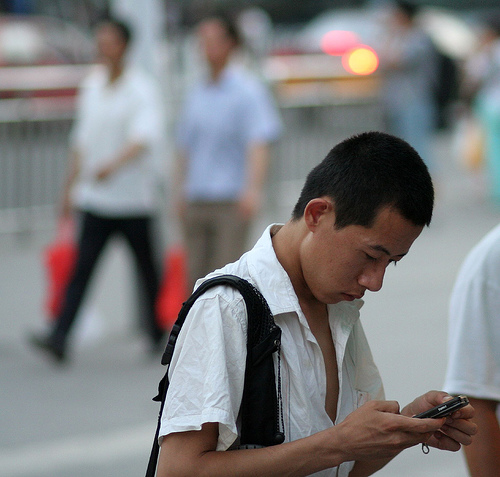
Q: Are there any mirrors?
A: No, there are no mirrors.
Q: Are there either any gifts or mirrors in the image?
A: No, there are no mirrors or gifts.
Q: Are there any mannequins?
A: No, there are no mannequins.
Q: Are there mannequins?
A: No, there are no mannequins.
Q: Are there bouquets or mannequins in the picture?
A: No, there are no mannequins or bouquets.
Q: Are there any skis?
A: No, there are no skis.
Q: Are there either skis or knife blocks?
A: No, there are no skis or knife blocks.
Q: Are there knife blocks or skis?
A: No, there are no skis or knife blocks.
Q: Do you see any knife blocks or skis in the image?
A: No, there are no skis or knife blocks.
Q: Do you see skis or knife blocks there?
A: No, there are no skis or knife blocks.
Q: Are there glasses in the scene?
A: No, there are no glasses.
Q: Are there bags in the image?
A: Yes, there is a bag.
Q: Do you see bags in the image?
A: Yes, there is a bag.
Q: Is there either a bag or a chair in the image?
A: Yes, there is a bag.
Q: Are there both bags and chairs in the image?
A: No, there is a bag but no chairs.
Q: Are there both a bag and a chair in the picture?
A: No, there is a bag but no chairs.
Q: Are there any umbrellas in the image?
A: No, there are no umbrellas.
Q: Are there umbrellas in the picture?
A: No, there are no umbrellas.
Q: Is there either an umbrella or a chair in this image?
A: No, there are no umbrellas or chairs.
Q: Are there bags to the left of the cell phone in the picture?
A: Yes, there is a bag to the left of the cell phone.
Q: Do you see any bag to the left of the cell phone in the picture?
A: Yes, there is a bag to the left of the cell phone.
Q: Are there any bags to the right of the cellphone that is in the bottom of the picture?
A: No, the bag is to the left of the cell phone.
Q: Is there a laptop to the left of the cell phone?
A: No, there is a bag to the left of the cell phone.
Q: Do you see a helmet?
A: No, there are no helmets.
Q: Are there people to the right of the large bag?
A: Yes, there is a person to the right of the bag.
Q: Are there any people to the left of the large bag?
A: No, the person is to the right of the bag.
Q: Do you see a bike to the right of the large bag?
A: No, there is a person to the right of the bag.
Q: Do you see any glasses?
A: No, there are no glasses.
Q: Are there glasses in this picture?
A: No, there are no glasses.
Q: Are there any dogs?
A: No, there are no dogs.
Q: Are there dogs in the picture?
A: No, there are no dogs.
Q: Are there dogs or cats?
A: No, there are no dogs or cats.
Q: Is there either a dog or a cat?
A: No, there are no dogs or cats.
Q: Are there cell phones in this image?
A: Yes, there is a cell phone.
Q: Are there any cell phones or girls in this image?
A: Yes, there is a cell phone.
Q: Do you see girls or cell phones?
A: Yes, there is a cell phone.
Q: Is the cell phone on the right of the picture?
A: Yes, the cell phone is on the right of the image.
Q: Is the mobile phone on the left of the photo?
A: No, the mobile phone is on the right of the image.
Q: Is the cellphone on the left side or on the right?
A: The cellphone is on the right of the image.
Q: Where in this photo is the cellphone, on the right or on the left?
A: The cellphone is on the right of the image.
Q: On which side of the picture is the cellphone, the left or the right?
A: The cellphone is on the right of the image.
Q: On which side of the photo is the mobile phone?
A: The mobile phone is on the right of the image.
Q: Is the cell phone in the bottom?
A: Yes, the cell phone is in the bottom of the image.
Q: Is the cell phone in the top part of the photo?
A: No, the cell phone is in the bottom of the image.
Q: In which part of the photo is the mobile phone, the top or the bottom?
A: The mobile phone is in the bottom of the image.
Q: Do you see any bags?
A: Yes, there is a bag.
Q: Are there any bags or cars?
A: Yes, there is a bag.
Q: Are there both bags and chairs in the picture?
A: No, there is a bag but no chairs.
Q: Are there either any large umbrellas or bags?
A: Yes, there is a large bag.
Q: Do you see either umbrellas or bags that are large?
A: Yes, the bag is large.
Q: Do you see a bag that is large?
A: Yes, there is a large bag.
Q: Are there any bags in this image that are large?
A: Yes, there is a bag that is large.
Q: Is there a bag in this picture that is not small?
A: Yes, there is a large bag.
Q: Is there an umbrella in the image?
A: No, there are no umbrellas.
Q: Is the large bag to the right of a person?
A: No, the bag is to the left of a person.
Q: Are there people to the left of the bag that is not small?
A: No, the person is to the right of the bag.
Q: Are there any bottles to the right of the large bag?
A: No, there is a person to the right of the bag.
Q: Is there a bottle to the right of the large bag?
A: No, there is a person to the right of the bag.